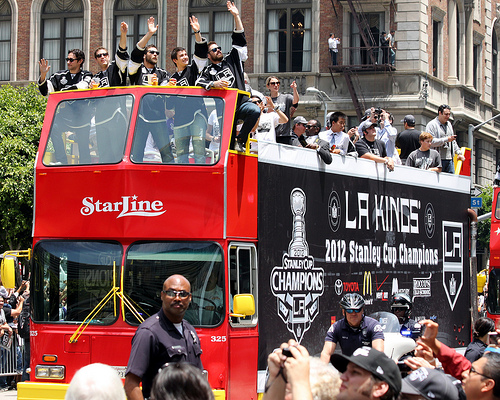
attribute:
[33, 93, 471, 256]
bus — red, black, yellow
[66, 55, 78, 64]
sunglasses — black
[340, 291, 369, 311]
helmet — black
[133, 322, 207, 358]
shirt — black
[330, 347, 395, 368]
cap — black, white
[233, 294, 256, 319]
mirror — yellow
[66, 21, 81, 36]
curtain — white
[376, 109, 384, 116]
camera — black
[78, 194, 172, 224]
logo — white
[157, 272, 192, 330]
man — bald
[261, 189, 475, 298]
sign — black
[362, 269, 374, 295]
logo — yellow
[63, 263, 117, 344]
windshield wiper — yellow